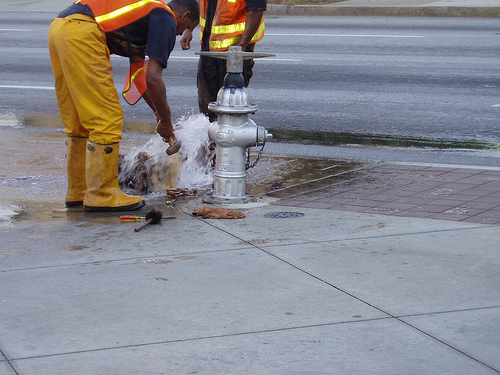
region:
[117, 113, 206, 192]
Water gushing out of the fire hydrant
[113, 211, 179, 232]
Metal tools on the ground next to the hydrant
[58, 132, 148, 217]
Yellow pair of boots with black soles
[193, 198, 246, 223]
Rubber glove laying on the ground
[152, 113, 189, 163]
Tool in the man's hands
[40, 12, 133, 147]
Bright yellow cargo pants tucked into boots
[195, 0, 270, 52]
Bright orange vest with yellow stripes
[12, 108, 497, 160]
Puddle in the road from the fire hydrant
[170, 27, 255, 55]
Man's hands by his side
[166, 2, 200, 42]
Man's head leaning over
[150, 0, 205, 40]
the head of a man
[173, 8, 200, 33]
the ear of a man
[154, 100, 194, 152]
the hand of a man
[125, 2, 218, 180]
the arm of a man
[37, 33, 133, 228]
the legs of a man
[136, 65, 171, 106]
the elbow of a man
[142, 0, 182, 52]
the shoulder of a man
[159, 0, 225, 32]
the hair of a man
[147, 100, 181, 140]
the wrist of a man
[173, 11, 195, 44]
the face of a man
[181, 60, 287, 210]
silver fire hydrant in photo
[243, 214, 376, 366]
lines on the cement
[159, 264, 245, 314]
gray cement on the ground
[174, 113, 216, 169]
water coming out of the hydrant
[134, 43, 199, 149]
arm of the man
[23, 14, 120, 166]
yellow pants on man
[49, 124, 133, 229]
yellow boots on man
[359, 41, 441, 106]
black street in photo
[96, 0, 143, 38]
orange and yellow outfit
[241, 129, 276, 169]
chain on the hydrant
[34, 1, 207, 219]
man is wearing yellow rubber boots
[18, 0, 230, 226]
man is wearing yellow pants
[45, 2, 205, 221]
man is wearing an orange safety vest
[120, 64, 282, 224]
fire hyrdant is gushing water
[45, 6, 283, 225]
man has opened fire hydrant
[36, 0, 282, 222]
man is wearing a blue shirt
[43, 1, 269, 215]
man is using a hammer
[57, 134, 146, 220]
yellow and black rubber boots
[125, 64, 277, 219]
water pouring out of fire hydrant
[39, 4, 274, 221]
two men working on a fire hydrant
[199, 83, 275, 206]
Silver colored fire hydrant.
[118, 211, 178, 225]
Screw driver on the ground.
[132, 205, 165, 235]
Mallet on the ground.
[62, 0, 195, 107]
Orange vest on the man.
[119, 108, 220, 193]
Water flowing from fire hydrant.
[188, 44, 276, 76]
Gray handle on the fire hydrant.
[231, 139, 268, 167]
chains on the fire hydrant.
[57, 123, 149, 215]
Yellow rubber boots on the feet.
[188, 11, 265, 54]
Yellow stripes on the vest.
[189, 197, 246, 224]
Brown glove on the hand.